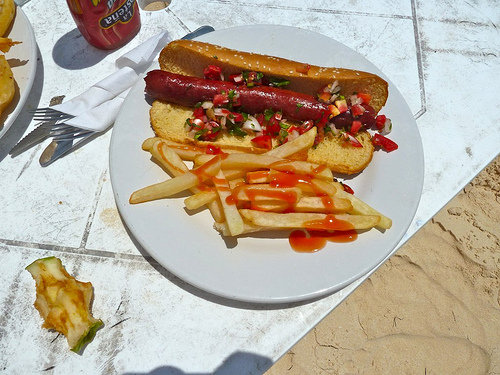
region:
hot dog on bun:
[142, 33, 399, 165]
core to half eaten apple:
[18, 248, 121, 364]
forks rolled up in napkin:
[8, 61, 222, 160]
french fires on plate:
[153, 116, 388, 278]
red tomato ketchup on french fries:
[160, 123, 370, 273]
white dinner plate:
[109, 26, 439, 278]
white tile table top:
[16, 146, 352, 358]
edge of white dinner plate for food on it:
[0, 1, 36, 137]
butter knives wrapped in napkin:
[3, 46, 128, 168]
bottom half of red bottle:
[52, 1, 155, 71]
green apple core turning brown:
[15, 250, 118, 352]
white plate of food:
[99, 27, 428, 289]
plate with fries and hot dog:
[117, 18, 478, 308]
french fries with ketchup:
[155, 137, 370, 257]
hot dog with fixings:
[162, 39, 378, 182]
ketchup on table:
[81, 0, 156, 39]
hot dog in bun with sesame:
[165, 32, 390, 172]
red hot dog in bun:
[145, 41, 384, 171]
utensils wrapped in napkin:
[17, 47, 154, 152]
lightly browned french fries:
[142, 142, 376, 254]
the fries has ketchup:
[136, 127, 390, 244]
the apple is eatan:
[25, 255, 102, 356]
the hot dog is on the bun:
[148, 39, 387, 180]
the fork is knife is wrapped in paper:
[6, 23, 215, 169]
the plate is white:
[107, 26, 426, 305]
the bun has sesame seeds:
[146, 40, 390, 172]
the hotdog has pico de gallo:
[188, 63, 397, 153]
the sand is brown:
[261, 155, 499, 373]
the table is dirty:
[3, 0, 499, 373]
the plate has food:
[109, 22, 424, 306]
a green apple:
[17, 240, 127, 359]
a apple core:
[7, 241, 115, 348]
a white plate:
[103, 20, 450, 329]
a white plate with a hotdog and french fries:
[68, 7, 420, 304]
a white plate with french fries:
[74, 10, 416, 322]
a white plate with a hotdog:
[140, 16, 420, 320]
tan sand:
[327, 184, 490, 371]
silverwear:
[3, 35, 259, 197]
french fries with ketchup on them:
[148, 133, 408, 313]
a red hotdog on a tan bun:
[135, 28, 420, 194]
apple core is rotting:
[16, 250, 98, 355]